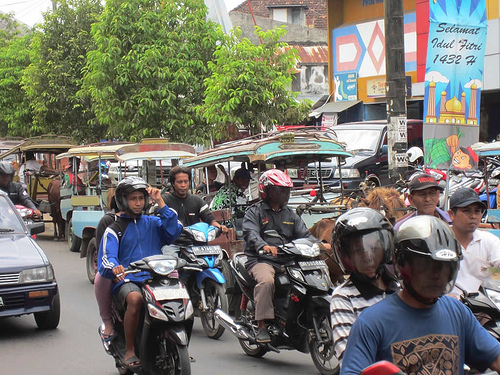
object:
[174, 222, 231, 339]
scooter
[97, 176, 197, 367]
man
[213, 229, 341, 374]
motorcycle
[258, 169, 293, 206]
helmet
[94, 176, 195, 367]
two people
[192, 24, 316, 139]
trees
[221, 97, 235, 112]
leaves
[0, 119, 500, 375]
steet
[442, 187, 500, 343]
man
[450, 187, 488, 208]
ball cap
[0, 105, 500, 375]
people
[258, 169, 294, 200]
grapic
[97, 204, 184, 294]
jacket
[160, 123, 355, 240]
bus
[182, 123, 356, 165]
top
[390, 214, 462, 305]
helmet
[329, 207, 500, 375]
top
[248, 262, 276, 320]
pants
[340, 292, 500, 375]
blue shirt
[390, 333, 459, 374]
design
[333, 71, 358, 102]
advertising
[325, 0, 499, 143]
building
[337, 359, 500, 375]
bike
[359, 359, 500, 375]
handle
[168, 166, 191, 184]
curly hair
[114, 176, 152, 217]
helmet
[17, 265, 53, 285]
headlight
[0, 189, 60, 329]
car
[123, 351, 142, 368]
flip flops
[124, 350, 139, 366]
feet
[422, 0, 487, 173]
banner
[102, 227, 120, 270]
white stripes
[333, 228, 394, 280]
visor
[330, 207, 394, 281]
helmet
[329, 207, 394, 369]
woman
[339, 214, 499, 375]
man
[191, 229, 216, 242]
headlights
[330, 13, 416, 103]
sign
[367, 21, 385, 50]
triangle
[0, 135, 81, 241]
cart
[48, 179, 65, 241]
horse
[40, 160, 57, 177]
man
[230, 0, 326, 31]
walls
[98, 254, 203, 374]
motorcycle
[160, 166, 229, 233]
man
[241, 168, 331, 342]
man